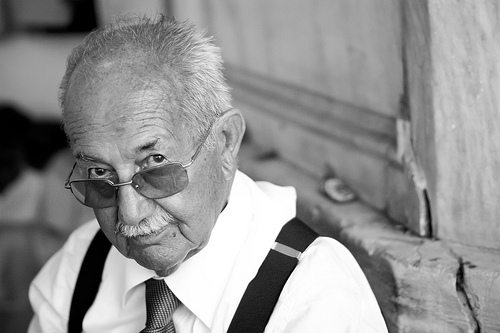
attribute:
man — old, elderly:
[19, 17, 409, 332]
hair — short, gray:
[71, 21, 214, 57]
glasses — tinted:
[63, 162, 190, 208]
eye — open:
[88, 164, 114, 182]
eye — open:
[143, 153, 167, 172]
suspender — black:
[221, 216, 329, 329]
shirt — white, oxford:
[27, 166, 389, 331]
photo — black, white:
[5, 1, 496, 332]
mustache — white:
[116, 211, 178, 238]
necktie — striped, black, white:
[139, 278, 179, 332]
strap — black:
[226, 220, 318, 333]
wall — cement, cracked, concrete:
[230, 6, 500, 332]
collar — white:
[164, 173, 269, 333]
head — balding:
[48, 8, 255, 274]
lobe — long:
[218, 153, 240, 180]